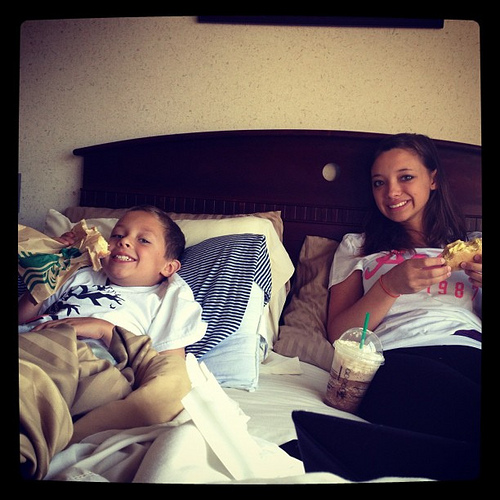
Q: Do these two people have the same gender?
A: No, they are both male and female.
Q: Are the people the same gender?
A: No, they are both male and female.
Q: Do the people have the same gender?
A: No, they are both male and female.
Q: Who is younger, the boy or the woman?
A: The boy is younger than the woman.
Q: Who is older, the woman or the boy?
A: The woman is older than the boy.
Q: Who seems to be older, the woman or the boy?
A: The woman is older than the boy.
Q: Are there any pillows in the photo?
A: Yes, there is a pillow.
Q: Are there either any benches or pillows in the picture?
A: Yes, there is a pillow.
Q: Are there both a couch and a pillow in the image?
A: No, there is a pillow but no couches.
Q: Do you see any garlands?
A: No, there are no garlands.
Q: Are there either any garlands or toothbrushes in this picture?
A: No, there are no garlands or toothbrushes.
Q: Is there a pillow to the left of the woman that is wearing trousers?
A: Yes, there is a pillow to the left of the woman.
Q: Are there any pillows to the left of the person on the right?
A: Yes, there is a pillow to the left of the woman.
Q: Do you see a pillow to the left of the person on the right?
A: Yes, there is a pillow to the left of the woman.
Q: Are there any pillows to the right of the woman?
A: No, the pillow is to the left of the woman.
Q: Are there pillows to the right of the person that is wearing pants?
A: No, the pillow is to the left of the woman.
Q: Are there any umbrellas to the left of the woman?
A: No, there is a pillow to the left of the woman.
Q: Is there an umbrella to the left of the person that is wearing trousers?
A: No, there is a pillow to the left of the woman.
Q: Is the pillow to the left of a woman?
A: Yes, the pillow is to the left of a woman.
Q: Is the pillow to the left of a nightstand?
A: No, the pillow is to the left of a woman.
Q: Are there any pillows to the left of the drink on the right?
A: Yes, there is a pillow to the left of the drink.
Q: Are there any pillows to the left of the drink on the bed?
A: Yes, there is a pillow to the left of the drink.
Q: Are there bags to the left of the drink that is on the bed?
A: No, there is a pillow to the left of the drink.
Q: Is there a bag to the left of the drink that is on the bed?
A: No, there is a pillow to the left of the drink.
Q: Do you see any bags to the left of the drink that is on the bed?
A: No, there is a pillow to the left of the drink.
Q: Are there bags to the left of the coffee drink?
A: No, there is a pillow to the left of the drink.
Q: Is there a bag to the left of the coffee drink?
A: No, there is a pillow to the left of the drink.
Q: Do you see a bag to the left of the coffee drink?
A: No, there is a pillow to the left of the drink.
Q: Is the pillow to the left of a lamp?
A: No, the pillow is to the left of the drink.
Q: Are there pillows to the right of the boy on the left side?
A: Yes, there is a pillow to the right of the boy.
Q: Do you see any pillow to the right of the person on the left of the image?
A: Yes, there is a pillow to the right of the boy.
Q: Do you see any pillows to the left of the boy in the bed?
A: No, the pillow is to the right of the boy.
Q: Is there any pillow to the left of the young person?
A: No, the pillow is to the right of the boy.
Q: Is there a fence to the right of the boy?
A: No, there is a pillow to the right of the boy.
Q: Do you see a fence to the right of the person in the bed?
A: No, there is a pillow to the right of the boy.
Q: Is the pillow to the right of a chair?
A: No, the pillow is to the right of the boy.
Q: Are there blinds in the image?
A: No, there are no blinds.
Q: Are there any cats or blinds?
A: No, there are no blinds or cats.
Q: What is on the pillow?
A: The pillow case is on the pillow.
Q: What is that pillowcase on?
A: The pillowcase is on the pillow.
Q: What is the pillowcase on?
A: The pillowcase is on the pillow.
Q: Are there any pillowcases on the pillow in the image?
A: Yes, there is a pillowcase on the pillow.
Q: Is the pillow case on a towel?
A: No, the pillow case is on the pillow.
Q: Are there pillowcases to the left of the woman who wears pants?
A: Yes, there is a pillowcase to the left of the woman.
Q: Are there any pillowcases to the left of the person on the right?
A: Yes, there is a pillowcase to the left of the woman.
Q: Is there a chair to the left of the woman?
A: No, there is a pillowcase to the left of the woman.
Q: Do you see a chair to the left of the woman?
A: No, there is a pillowcase to the left of the woman.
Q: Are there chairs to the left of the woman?
A: No, there is a pillowcase to the left of the woman.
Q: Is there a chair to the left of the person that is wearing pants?
A: No, there is a pillowcase to the left of the woman.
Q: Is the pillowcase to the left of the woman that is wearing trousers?
A: Yes, the pillowcase is to the left of the woman.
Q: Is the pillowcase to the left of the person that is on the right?
A: Yes, the pillowcase is to the left of the woman.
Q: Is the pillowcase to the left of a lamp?
A: No, the pillowcase is to the left of the woman.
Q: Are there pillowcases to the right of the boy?
A: Yes, there is a pillowcase to the right of the boy.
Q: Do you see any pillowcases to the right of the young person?
A: Yes, there is a pillowcase to the right of the boy.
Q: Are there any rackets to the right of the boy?
A: No, there is a pillowcase to the right of the boy.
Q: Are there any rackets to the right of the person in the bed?
A: No, there is a pillowcase to the right of the boy.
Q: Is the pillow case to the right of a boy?
A: Yes, the pillow case is to the right of a boy.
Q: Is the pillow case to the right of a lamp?
A: No, the pillow case is to the right of a boy.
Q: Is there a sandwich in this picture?
A: Yes, there is a sandwich.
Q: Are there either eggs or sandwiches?
A: Yes, there is a sandwich.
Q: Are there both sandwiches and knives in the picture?
A: No, there is a sandwich but no knives.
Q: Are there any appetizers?
A: No, there are no appetizers.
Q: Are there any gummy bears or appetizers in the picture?
A: No, there are no appetizers or gummy bears.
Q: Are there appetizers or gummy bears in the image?
A: No, there are no appetizers or gummy bears.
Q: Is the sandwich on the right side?
A: Yes, the sandwich is on the right of the image.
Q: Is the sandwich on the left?
A: No, the sandwich is on the right of the image.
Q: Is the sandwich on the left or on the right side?
A: The sandwich is on the right of the image.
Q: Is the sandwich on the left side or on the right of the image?
A: The sandwich is on the right of the image.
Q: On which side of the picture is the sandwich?
A: The sandwich is on the right of the image.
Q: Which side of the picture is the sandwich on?
A: The sandwich is on the right of the image.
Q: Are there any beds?
A: Yes, there is a bed.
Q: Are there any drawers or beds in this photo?
A: Yes, there is a bed.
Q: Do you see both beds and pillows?
A: Yes, there are both a bed and a pillow.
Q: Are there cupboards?
A: No, there are no cupboards.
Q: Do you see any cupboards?
A: No, there are no cupboards.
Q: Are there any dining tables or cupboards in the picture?
A: No, there are no cupboards or dining tables.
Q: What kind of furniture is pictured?
A: The furniture is a bed.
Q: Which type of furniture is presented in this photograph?
A: The furniture is a bed.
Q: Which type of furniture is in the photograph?
A: The furniture is a bed.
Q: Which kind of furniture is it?
A: The piece of furniture is a bed.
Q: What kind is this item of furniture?
A: This is a bed.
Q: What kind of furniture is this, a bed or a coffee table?
A: This is a bed.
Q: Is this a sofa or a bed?
A: This is a bed.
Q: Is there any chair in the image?
A: No, there are no chairs.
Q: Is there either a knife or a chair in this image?
A: No, there are no chairs or knives.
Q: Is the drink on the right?
A: Yes, the drink is on the right of the image.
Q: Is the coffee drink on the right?
A: Yes, the drink is on the right of the image.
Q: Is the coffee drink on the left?
A: No, the drink is on the right of the image.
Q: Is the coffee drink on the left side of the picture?
A: No, the drink is on the right of the image.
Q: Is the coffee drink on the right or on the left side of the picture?
A: The drink is on the right of the image.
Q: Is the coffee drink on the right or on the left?
A: The drink is on the right of the image.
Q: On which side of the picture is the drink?
A: The drink is on the right of the image.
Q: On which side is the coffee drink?
A: The drink is on the right of the image.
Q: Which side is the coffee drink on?
A: The drink is on the right of the image.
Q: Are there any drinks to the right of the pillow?
A: Yes, there is a drink to the right of the pillow.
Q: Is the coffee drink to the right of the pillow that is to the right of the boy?
A: Yes, the drink is to the right of the pillow.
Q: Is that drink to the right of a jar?
A: No, the drink is to the right of the pillow.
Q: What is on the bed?
A: The drink is on the bed.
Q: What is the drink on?
A: The drink is on the bed.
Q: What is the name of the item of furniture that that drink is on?
A: The piece of furniture is a bed.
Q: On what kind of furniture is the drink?
A: The drink is on the bed.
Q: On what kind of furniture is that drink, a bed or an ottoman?
A: The drink is on a bed.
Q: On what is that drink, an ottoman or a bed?
A: The drink is on a bed.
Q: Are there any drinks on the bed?
A: Yes, there is a drink on the bed.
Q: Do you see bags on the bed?
A: No, there is a drink on the bed.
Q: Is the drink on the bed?
A: Yes, the drink is on the bed.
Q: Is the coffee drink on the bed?
A: Yes, the drink is on the bed.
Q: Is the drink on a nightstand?
A: No, the drink is on the bed.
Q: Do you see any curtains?
A: No, there are no curtains.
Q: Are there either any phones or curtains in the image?
A: No, there are no curtains or phones.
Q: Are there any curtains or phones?
A: No, there are no curtains or phones.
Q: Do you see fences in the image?
A: No, there are no fences.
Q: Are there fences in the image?
A: No, there are no fences.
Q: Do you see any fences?
A: No, there are no fences.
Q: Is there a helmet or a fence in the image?
A: No, there are no fences or helmets.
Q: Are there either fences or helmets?
A: No, there are no fences or helmets.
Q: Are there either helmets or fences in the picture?
A: No, there are no fences or helmets.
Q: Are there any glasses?
A: No, there are no glasses.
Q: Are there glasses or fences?
A: No, there are no glasses or fences.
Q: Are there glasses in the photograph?
A: No, there are no glasses.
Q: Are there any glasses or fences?
A: No, there are no glasses or fences.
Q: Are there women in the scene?
A: Yes, there is a woman.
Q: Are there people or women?
A: Yes, there is a woman.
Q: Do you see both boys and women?
A: Yes, there are both a woman and a boy.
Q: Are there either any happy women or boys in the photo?
A: Yes, there is a happy woman.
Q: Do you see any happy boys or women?
A: Yes, there is a happy woman.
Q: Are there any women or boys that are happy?
A: Yes, the woman is happy.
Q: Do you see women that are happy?
A: Yes, there is a happy woman.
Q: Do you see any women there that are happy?
A: Yes, there is a woman that is happy.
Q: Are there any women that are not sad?
A: Yes, there is a happy woman.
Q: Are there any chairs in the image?
A: No, there are no chairs.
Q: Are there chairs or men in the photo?
A: No, there are no chairs or men.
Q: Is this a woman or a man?
A: This is a woman.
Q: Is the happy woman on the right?
A: Yes, the woman is on the right of the image.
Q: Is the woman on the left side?
A: No, the woman is on the right of the image.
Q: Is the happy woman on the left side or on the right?
A: The woman is on the right of the image.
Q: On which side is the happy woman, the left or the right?
A: The woman is on the right of the image.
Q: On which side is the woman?
A: The woman is on the right of the image.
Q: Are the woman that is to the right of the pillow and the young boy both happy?
A: Yes, both the woman and the boy are happy.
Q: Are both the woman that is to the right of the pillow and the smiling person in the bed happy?
A: Yes, both the woman and the boy are happy.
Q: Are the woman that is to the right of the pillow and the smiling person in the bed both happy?
A: Yes, both the woman and the boy are happy.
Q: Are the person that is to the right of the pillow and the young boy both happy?
A: Yes, both the woman and the boy are happy.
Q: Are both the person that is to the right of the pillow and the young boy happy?
A: Yes, both the woman and the boy are happy.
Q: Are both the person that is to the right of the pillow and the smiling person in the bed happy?
A: Yes, both the woman and the boy are happy.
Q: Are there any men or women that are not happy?
A: No, there is a woman but she is happy.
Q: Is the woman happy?
A: Yes, the woman is happy.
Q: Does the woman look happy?
A: Yes, the woman is happy.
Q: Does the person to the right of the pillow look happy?
A: Yes, the woman is happy.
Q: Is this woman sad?
A: No, the woman is happy.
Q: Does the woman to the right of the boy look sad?
A: No, the woman is happy.